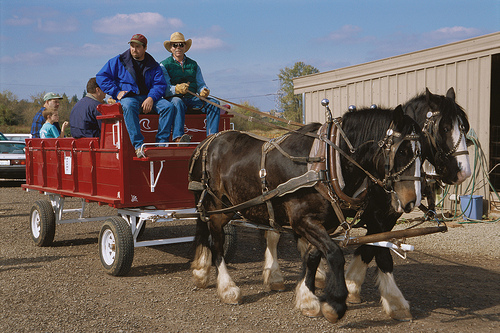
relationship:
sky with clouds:
[2, 1, 499, 111] [196, 37, 224, 47]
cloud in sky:
[95, 12, 192, 34] [191, 2, 497, 57]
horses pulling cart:
[184, 77, 484, 327] [15, 96, 240, 279]